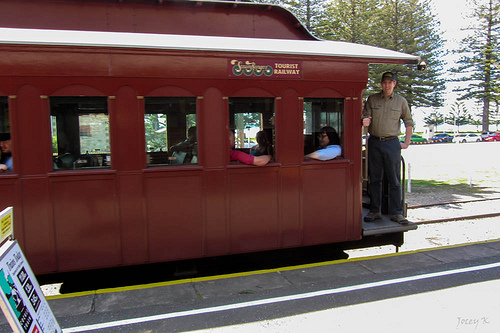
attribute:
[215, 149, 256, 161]
shirt —  pink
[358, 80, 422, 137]
shirt — brown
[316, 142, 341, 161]
shirt —  blue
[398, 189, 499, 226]
track —  train's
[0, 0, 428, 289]
train — red,  maroon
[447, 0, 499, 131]
tree — tall, pine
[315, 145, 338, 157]
shirt —  blue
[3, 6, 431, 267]
train — maroon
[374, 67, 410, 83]
hat —  blue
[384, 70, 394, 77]
lettering — yellow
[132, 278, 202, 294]
yellow line —  yellow,  platform's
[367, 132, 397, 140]
belt — brown, leather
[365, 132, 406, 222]
blue pants —  blue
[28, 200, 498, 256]
line —  yellow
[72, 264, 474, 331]
train platform —  train's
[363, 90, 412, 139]
shirt —  tan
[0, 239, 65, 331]
sign —  for marketing